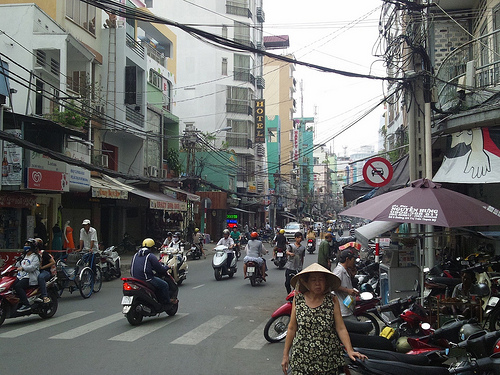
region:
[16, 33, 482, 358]
Some people are out in the city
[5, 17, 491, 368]
Some people are on their motorbikes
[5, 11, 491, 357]
Some people are using the street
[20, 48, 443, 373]
Some people are going to work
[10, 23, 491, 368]
Some people are doing some shopping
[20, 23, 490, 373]
Some people are wearing hats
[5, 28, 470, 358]
Some people are obeying the law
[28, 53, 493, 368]
Some people are out in the daytime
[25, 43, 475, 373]
Some people are having a great time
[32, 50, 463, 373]
Some people are enjoying their day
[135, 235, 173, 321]
person on a motorcycle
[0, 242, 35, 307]
person on a motorcycle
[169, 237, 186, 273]
person on a motorcycle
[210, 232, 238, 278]
person on a motorcycle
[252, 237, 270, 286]
person on a motorcycle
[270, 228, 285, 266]
person on a motorcycle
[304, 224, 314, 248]
person on a motorcycle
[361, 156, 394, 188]
traffic sign indicating no cars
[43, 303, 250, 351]
cross walk for pedestrians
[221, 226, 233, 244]
person wearing a white helmet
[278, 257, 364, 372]
Woman in a black dress with flowers on it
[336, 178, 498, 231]
Purple umbrella with white letters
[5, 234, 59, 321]
Two people riding a motorcycle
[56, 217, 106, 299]
Man driving a pedal cart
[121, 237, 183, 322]
Man on motorcycle with yellow helmet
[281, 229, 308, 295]
Person with gray shirt and black pants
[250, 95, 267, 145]
Black sign with HOTEL written in yellow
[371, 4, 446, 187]
Tangle of wires on pole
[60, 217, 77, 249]
Mannequin wearing an orange dress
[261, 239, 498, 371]
Motorcycles parked in large group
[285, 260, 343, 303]
person wearing a sun hat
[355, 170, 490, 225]
black umbrella with white text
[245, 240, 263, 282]
person on a motorcycle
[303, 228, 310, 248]
person on a motorcycle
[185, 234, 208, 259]
person on a motorcycle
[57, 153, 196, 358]
this is an asian city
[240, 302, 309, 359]
this is a woman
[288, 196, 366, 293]
this is a hat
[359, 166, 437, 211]
this is an umbrella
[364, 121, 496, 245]
the umbrella is purple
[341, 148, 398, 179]
this is a round sign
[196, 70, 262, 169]
this is a building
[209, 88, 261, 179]
this is a window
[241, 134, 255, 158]
this is a balcony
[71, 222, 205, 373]
this is a motorcylce